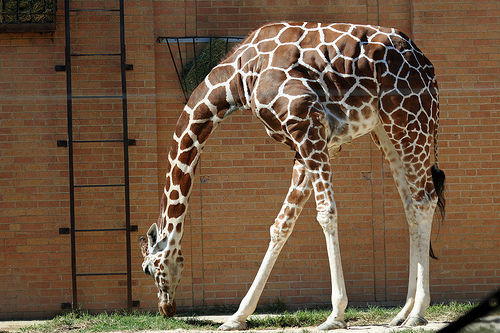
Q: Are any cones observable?
A: No, there are no cones.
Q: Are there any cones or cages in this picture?
A: No, there are no cones or cages.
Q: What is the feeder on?
A: The feeder is on the wall.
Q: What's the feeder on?
A: The feeder is on the wall.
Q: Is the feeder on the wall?
A: Yes, the feeder is on the wall.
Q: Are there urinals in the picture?
A: No, there are no urinals.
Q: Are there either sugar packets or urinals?
A: No, there are no urinals or sugar packets.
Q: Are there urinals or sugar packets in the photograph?
A: No, there are no urinals or sugar packets.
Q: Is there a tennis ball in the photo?
A: No, there are no tennis balls.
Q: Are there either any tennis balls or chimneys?
A: No, there are no tennis balls or chimneys.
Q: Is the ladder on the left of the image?
A: Yes, the ladder is on the left of the image.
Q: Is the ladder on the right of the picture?
A: No, the ladder is on the left of the image.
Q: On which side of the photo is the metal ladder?
A: The ladder is on the left of the image.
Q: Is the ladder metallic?
A: Yes, the ladder is metallic.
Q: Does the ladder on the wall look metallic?
A: Yes, the ladder is metallic.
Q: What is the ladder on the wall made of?
A: The ladder is made of metal.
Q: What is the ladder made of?
A: The ladder is made of metal.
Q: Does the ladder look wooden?
A: No, the ladder is metallic.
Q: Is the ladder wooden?
A: No, the ladder is metallic.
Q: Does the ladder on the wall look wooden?
A: No, the ladder is metallic.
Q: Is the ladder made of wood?
A: No, the ladder is made of metal.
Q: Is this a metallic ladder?
A: Yes, this is a metallic ladder.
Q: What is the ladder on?
A: The ladder is on the wall.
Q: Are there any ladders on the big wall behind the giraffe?
A: Yes, there is a ladder on the wall.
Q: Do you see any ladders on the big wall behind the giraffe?
A: Yes, there is a ladder on the wall.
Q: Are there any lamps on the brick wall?
A: No, there is a ladder on the wall.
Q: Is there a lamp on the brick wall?
A: No, there is a ladder on the wall.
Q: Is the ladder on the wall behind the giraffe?
A: Yes, the ladder is on the wall.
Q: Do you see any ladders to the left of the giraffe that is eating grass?
A: Yes, there is a ladder to the left of the giraffe.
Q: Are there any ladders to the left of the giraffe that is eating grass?
A: Yes, there is a ladder to the left of the giraffe.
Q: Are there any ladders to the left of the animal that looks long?
A: Yes, there is a ladder to the left of the giraffe.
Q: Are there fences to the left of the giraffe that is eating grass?
A: No, there is a ladder to the left of the giraffe.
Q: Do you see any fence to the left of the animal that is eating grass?
A: No, there is a ladder to the left of the giraffe.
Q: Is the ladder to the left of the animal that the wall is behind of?
A: Yes, the ladder is to the left of the giraffe.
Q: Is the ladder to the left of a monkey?
A: No, the ladder is to the left of the giraffe.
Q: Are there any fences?
A: No, there are no fences.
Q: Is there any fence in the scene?
A: No, there are no fences.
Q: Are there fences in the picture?
A: No, there are no fences.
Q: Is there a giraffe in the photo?
A: Yes, there is a giraffe.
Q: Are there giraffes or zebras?
A: Yes, there is a giraffe.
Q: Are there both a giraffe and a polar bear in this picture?
A: No, there is a giraffe but no polar bears.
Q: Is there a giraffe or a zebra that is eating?
A: Yes, the giraffe is eating.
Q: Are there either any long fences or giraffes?
A: Yes, there is a long giraffe.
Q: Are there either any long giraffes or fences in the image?
A: Yes, there is a long giraffe.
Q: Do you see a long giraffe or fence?
A: Yes, there is a long giraffe.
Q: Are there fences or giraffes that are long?
A: Yes, the giraffe is long.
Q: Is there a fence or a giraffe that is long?
A: Yes, the giraffe is long.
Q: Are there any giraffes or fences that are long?
A: Yes, the giraffe is long.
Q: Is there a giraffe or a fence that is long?
A: Yes, the giraffe is long.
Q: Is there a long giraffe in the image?
A: Yes, there is a long giraffe.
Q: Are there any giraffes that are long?
A: Yes, there is a giraffe that is long.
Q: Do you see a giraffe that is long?
A: Yes, there is a giraffe that is long.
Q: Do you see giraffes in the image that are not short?
A: Yes, there is a long giraffe.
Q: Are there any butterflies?
A: No, there are no butterflies.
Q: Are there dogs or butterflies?
A: No, there are no butterflies or dogs.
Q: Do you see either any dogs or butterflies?
A: No, there are no butterflies or dogs.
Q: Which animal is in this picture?
A: The animal is a giraffe.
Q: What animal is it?
A: The animal is a giraffe.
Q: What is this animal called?
A: This is a giraffe.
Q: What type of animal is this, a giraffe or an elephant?
A: This is a giraffe.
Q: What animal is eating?
A: The animal is a giraffe.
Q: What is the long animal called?
A: The animal is a giraffe.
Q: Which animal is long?
A: The animal is a giraffe.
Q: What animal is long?
A: The animal is a giraffe.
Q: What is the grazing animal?
A: The animal is a giraffe.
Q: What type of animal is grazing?
A: The animal is a giraffe.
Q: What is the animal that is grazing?
A: The animal is a giraffe.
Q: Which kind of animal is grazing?
A: The animal is a giraffe.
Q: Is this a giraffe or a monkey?
A: This is a giraffe.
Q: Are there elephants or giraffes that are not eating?
A: No, there is a giraffe but it is eating.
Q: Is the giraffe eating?
A: Yes, the giraffe is eating.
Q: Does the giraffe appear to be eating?
A: Yes, the giraffe is eating.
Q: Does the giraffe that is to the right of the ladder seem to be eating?
A: Yes, the giraffe is eating.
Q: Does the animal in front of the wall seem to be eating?
A: Yes, the giraffe is eating.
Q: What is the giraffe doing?
A: The giraffe is eating.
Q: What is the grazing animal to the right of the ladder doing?
A: The giraffe is eating.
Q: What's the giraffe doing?
A: The giraffe is eating.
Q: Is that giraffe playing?
A: No, the giraffe is eating.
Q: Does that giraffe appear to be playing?
A: No, the giraffe is eating.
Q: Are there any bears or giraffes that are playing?
A: No, there is a giraffe but it is eating.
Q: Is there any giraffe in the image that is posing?
A: No, there is a giraffe but it is eating.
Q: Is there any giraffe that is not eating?
A: No, there is a giraffe but it is eating.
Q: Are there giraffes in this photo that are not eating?
A: No, there is a giraffe but it is eating.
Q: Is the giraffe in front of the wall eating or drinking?
A: The giraffe is eating.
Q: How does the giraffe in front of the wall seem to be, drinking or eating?
A: The giraffe is eating.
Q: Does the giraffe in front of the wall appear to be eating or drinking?
A: The giraffe is eating.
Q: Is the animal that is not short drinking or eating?
A: The giraffe is eating.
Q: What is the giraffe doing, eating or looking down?
A: The giraffe is eating.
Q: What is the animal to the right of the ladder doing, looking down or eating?
A: The giraffe is eating.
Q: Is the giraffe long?
A: Yes, the giraffe is long.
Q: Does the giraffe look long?
A: Yes, the giraffe is long.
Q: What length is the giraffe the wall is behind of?
A: The giraffe is long.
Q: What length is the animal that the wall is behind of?
A: The giraffe is long.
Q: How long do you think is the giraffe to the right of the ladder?
A: The giraffe is long.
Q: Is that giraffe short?
A: No, the giraffe is long.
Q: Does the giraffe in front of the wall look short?
A: No, the giraffe is long.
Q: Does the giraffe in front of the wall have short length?
A: No, the giraffe is long.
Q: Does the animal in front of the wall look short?
A: No, the giraffe is long.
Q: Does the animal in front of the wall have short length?
A: No, the giraffe is long.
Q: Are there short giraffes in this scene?
A: No, there is a giraffe but it is long.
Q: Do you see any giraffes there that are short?
A: No, there is a giraffe but it is long.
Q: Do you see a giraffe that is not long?
A: No, there is a giraffe but it is long.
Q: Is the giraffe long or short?
A: The giraffe is long.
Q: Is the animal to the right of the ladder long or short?
A: The giraffe is long.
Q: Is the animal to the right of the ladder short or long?
A: The giraffe is long.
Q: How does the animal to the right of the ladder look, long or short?
A: The giraffe is long.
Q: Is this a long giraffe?
A: Yes, this is a long giraffe.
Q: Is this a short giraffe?
A: No, this is a long giraffe.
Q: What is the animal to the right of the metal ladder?
A: The animal is a giraffe.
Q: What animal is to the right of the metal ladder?
A: The animal is a giraffe.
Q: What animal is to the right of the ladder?
A: The animal is a giraffe.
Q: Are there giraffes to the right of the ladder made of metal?
A: Yes, there is a giraffe to the right of the ladder.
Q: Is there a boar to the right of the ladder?
A: No, there is a giraffe to the right of the ladder.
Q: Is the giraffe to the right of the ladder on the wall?
A: Yes, the giraffe is to the right of the ladder.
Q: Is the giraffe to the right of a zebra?
A: No, the giraffe is to the right of the ladder.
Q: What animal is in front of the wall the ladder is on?
A: The giraffe is in front of the wall.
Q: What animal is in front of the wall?
A: The giraffe is in front of the wall.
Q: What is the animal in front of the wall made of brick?
A: The animal is a giraffe.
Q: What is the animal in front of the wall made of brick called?
A: The animal is a giraffe.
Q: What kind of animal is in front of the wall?
A: The animal is a giraffe.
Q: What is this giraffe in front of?
A: The giraffe is in front of the wall.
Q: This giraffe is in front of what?
A: The giraffe is in front of the wall.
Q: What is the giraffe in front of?
A: The giraffe is in front of the wall.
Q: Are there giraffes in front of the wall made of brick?
A: Yes, there is a giraffe in front of the wall.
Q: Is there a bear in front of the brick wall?
A: No, there is a giraffe in front of the wall.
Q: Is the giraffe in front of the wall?
A: Yes, the giraffe is in front of the wall.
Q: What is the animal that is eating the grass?
A: The animal is a giraffe.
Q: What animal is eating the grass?
A: The animal is a giraffe.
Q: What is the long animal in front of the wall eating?
A: The giraffe is eating grass.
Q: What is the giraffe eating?
A: The giraffe is eating grass.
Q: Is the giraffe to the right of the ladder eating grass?
A: Yes, the giraffe is eating grass.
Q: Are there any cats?
A: No, there are no cats.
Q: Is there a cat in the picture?
A: No, there are no cats.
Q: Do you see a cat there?
A: No, there are no cats.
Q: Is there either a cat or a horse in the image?
A: No, there are no cats or horses.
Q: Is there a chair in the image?
A: No, there are no chairs.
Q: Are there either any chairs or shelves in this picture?
A: No, there are no chairs or shelves.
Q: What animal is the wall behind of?
A: The wall is behind the giraffe.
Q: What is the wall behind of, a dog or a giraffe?
A: The wall is behind a giraffe.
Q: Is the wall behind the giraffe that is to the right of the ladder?
A: Yes, the wall is behind the giraffe.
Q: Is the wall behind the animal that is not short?
A: Yes, the wall is behind the giraffe.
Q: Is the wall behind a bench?
A: No, the wall is behind the giraffe.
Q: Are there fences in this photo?
A: No, there are no fences.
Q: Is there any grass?
A: Yes, there is grass.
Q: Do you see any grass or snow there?
A: Yes, there is grass.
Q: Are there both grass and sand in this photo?
A: No, there is grass but no sand.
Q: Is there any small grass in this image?
A: Yes, there is small grass.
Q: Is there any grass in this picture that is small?
A: Yes, there is grass that is small.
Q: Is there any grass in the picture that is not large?
A: Yes, there is small grass.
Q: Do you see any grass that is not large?
A: Yes, there is small grass.